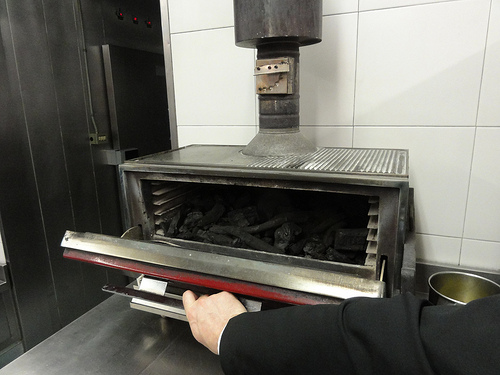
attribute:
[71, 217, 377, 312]
door — heater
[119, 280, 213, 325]
handle — red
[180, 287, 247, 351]
hand — white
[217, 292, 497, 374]
sleeve — black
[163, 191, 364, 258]
sticks — wood 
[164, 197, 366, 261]
charcoal — black  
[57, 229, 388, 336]
door — open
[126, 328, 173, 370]
metal — grey, shiny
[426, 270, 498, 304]
bowl — silver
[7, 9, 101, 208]
panels — black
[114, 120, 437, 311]
oven — small, little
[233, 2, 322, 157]
pipe — metal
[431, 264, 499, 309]
bowl — stainless steel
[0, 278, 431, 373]
counter top — steel 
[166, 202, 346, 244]
wood — burnt 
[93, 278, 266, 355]
handle — silver